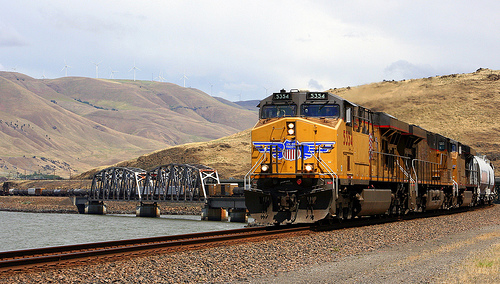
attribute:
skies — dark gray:
[0, 0, 482, 100]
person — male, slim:
[384, 83, 482, 235]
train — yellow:
[252, 88, 497, 232]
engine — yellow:
[246, 88, 477, 230]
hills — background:
[0, 66, 260, 178]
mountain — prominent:
[3, 69, 498, 179]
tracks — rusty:
[31, 220, 355, 272]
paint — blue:
[258, 140, 334, 160]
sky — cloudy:
[4, 2, 484, 80]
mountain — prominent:
[89, 130, 250, 211]